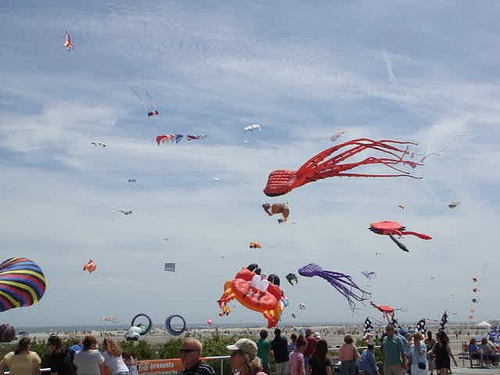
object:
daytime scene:
[0, 2, 499, 373]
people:
[0, 317, 498, 372]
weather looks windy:
[1, 0, 499, 374]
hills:
[17, 323, 162, 337]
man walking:
[381, 322, 409, 374]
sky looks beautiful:
[1, 1, 499, 324]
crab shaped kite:
[261, 134, 425, 194]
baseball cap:
[226, 336, 259, 354]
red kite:
[262, 137, 425, 197]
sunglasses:
[174, 347, 198, 353]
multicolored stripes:
[0, 255, 45, 312]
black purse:
[413, 344, 428, 370]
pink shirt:
[285, 350, 308, 374]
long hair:
[244, 353, 263, 373]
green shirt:
[379, 335, 403, 363]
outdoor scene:
[1, 1, 499, 375]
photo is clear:
[1, 0, 499, 374]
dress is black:
[434, 333, 450, 374]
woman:
[98, 333, 131, 374]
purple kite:
[296, 262, 371, 315]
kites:
[2, 14, 474, 337]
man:
[375, 318, 408, 372]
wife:
[406, 325, 431, 371]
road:
[367, 345, 479, 361]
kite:
[213, 259, 294, 330]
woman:
[218, 336, 267, 370]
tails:
[289, 129, 419, 189]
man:
[167, 331, 226, 373]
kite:
[0, 254, 46, 305]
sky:
[5, 2, 497, 321]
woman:
[404, 327, 427, 373]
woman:
[289, 330, 309, 373]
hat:
[226, 335, 261, 354]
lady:
[224, 335, 269, 373]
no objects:
[419, 95, 482, 123]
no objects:
[452, 126, 482, 179]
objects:
[215, 140, 433, 327]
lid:
[225, 336, 257, 355]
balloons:
[215, 136, 430, 327]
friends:
[174, 332, 264, 372]